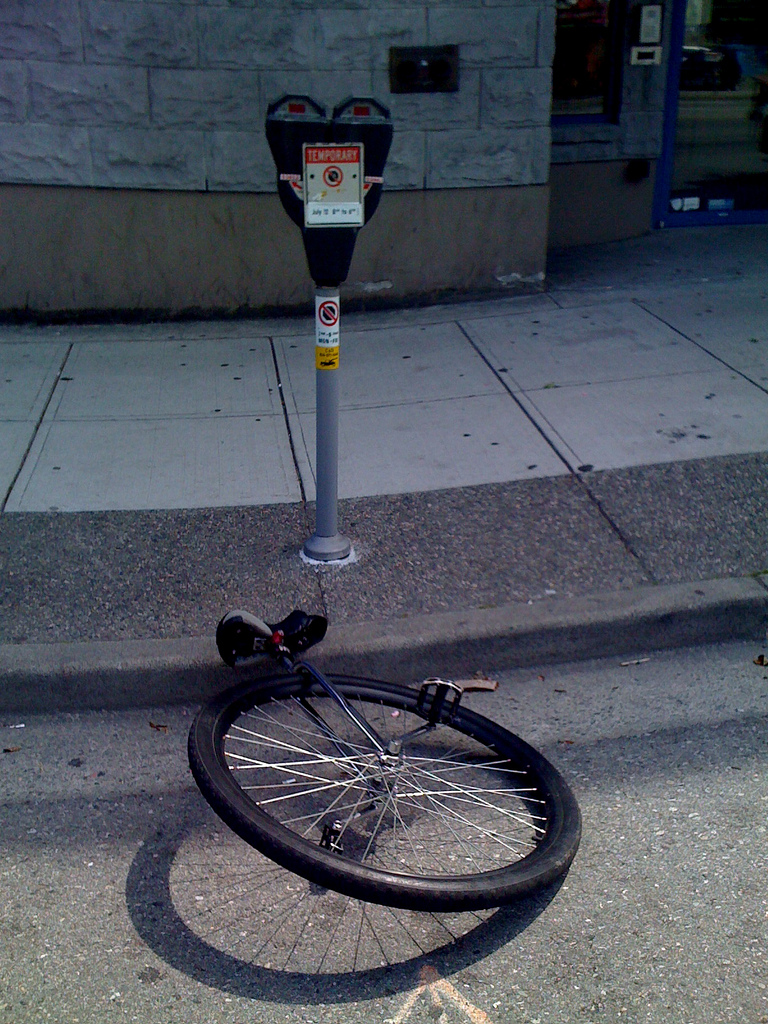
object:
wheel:
[184, 664, 585, 913]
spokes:
[401, 751, 529, 775]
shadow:
[124, 817, 583, 1004]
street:
[2, 636, 768, 1021]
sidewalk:
[0, 297, 768, 717]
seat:
[215, 607, 329, 666]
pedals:
[415, 675, 464, 727]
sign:
[301, 142, 365, 228]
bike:
[184, 605, 587, 914]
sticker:
[316, 296, 340, 371]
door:
[648, 0, 768, 233]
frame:
[649, 208, 767, 230]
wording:
[308, 148, 358, 163]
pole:
[302, 287, 353, 564]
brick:
[0, 187, 554, 326]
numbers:
[288, 102, 306, 114]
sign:
[315, 296, 341, 348]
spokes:
[279, 792, 396, 826]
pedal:
[318, 821, 345, 854]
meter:
[265, 92, 396, 290]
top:
[626, 886, 698, 996]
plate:
[388, 44, 460, 93]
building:
[0, 0, 768, 338]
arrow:
[365, 953, 517, 1024]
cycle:
[187, 684, 585, 913]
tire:
[185, 664, 585, 916]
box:
[629, 46, 663, 67]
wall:
[4, 2, 547, 291]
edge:
[483, 614, 629, 643]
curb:
[0, 568, 768, 715]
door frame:
[649, 0, 691, 232]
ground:
[593, 650, 767, 1020]